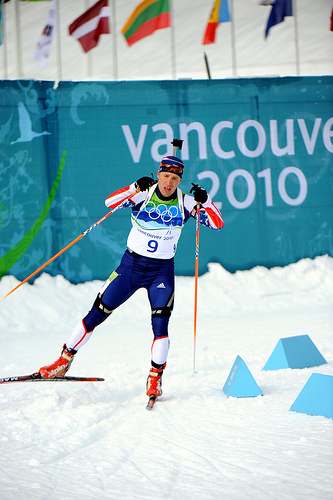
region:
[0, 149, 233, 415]
Olympic skier during 2010 Olympics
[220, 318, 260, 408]
a blue marker on top of snow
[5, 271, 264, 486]
snow on mountain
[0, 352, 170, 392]
man wearing orange ski boots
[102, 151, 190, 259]
man wearing white and blue number 9 with olympic symbols shirt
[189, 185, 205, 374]
man with orange ski pole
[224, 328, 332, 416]
group of blue triangle markers on ground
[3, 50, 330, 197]
blue gate with 2010 vancouver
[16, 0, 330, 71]
a bunch of different countries flags flying high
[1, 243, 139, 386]
skier's left leg is flex with boot and ski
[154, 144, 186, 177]
man has blue cap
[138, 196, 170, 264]
man is number 9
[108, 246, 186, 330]
man has blue pants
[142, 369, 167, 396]
man has red shoes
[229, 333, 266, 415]
light blue barriers next to man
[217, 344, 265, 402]
barriers are small and triangular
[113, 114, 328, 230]
sign is white behind man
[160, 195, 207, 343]
man holds orange ski poles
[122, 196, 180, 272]
man's shirt is white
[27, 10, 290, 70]
national flags behind wall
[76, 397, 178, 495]
the snow is white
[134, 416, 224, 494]
the snow is white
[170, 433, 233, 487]
the snow is white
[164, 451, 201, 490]
the snow is white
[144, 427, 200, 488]
the snow is white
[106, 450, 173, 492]
the snow is white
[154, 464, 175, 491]
the snow is white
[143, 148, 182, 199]
face of the person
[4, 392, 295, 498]
a beautiful view of ice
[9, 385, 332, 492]
cool ice for skating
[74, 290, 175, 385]
legs of the person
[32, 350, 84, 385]
shoe of the person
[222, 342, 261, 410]
a small object in ice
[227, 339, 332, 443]
a beautiful group of blue objects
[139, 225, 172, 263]
number of the player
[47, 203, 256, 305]
two sticks holding by person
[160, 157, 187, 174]
cap of the person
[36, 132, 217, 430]
skier coming down slope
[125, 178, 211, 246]
skier carring a backpack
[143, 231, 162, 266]
9 on the skier's bib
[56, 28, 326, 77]
flags over the Vancouver 2010 sign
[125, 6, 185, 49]
flag is orange, green and red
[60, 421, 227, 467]
ground is covered in snow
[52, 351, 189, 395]
ski boots are orange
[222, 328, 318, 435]
three blue barriers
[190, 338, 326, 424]
barriers' shape is triangle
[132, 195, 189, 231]
Olympic symbol on the bib